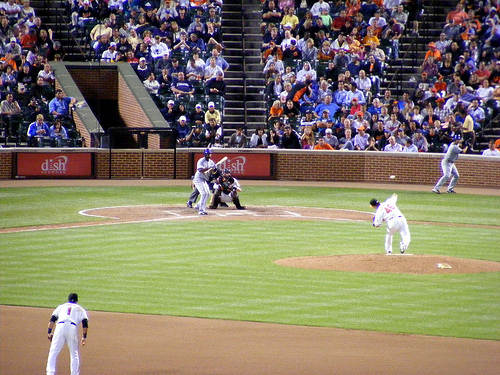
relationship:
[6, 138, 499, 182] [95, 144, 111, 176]
wall of bricks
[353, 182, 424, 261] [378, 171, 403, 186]
pitcher pitching ball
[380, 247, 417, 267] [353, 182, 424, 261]
mound of pitcher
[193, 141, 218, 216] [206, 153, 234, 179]
person getting ready to bat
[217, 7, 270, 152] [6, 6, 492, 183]
stairs going up stadium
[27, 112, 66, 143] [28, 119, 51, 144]
people wearing shirts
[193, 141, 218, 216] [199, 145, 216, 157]
person wearing helmet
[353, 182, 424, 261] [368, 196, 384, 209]
person wearing hat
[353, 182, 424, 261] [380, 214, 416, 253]
person wearing pants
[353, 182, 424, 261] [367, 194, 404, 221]
person wearing shirt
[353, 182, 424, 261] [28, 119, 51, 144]
person wearing shirts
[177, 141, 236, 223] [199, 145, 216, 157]
person wearing helmet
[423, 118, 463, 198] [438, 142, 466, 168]
person wearing shirt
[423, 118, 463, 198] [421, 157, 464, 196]
person wearing gray pant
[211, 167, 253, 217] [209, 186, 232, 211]
catcher has shin guards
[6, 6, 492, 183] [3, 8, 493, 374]
spectator watching game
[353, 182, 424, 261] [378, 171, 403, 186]
player pitches baseball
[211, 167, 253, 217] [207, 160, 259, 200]
player ready to catch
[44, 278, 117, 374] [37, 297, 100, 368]
player in white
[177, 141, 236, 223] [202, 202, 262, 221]
player at home plate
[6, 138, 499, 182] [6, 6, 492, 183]
barricade protecting spectator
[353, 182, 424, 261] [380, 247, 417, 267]
man on mound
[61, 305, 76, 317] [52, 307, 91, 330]
1 on a jersey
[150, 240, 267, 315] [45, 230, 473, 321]
grass in outfield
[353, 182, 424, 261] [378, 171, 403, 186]
pitcher threw ball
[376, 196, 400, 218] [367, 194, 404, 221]
46 on jersey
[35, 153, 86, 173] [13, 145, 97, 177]
dish logo on sign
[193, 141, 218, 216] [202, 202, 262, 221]
person behind home plate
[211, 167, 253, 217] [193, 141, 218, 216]
catcher behind person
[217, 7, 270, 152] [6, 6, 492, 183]
steps in stadium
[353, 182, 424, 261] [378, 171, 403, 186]
man pitching ball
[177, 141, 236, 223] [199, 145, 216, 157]
batter wearing helmet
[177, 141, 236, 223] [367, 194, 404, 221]
person with shirt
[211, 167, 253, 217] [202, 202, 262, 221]
catcher behind home plate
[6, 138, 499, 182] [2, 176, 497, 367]
wall around field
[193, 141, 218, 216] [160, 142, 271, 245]
person on deck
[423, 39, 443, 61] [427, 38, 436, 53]
person with orange cap